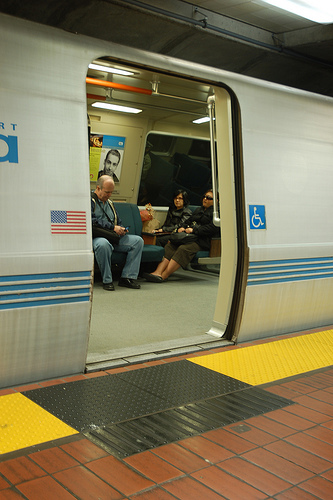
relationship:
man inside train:
[91, 175, 143, 291] [1, 9, 333, 388]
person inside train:
[150, 193, 218, 280] [1, 9, 333, 388]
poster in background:
[89, 132, 126, 188] [91, 97, 214, 296]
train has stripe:
[1, 9, 333, 388] [1, 269, 94, 311]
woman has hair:
[156, 190, 200, 247] [165, 190, 188, 211]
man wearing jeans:
[91, 175, 143, 291] [93, 234, 146, 283]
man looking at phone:
[91, 175, 143, 291] [121, 225, 129, 237]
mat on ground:
[22, 357, 296, 461] [0, 323, 332, 500]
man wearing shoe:
[91, 175, 143, 291] [122, 279, 139, 288]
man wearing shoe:
[91, 175, 143, 291] [104, 281, 117, 290]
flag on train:
[52, 211, 89, 234] [1, 9, 333, 388]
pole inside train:
[207, 95, 223, 227] [1, 9, 333, 388]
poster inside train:
[89, 132, 126, 188] [1, 9, 333, 388]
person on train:
[150, 193, 218, 280] [1, 9, 333, 388]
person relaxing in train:
[150, 193, 218, 280] [1, 9, 333, 388]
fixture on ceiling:
[92, 103, 143, 115] [89, 64, 212, 131]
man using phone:
[91, 175, 143, 291] [121, 225, 129, 237]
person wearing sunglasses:
[150, 193, 218, 280] [202, 195, 214, 204]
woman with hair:
[156, 190, 200, 247] [165, 190, 188, 211]